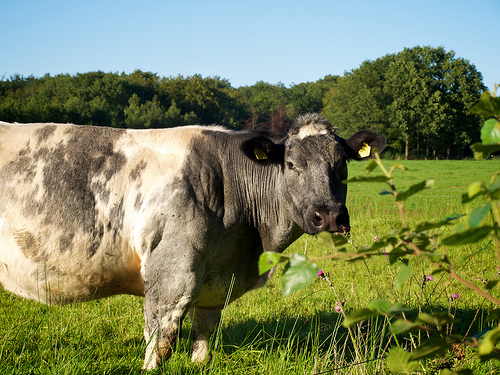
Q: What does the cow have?
A: Spots.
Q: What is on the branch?
A: Leaves.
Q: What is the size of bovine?
A: Very large.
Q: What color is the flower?
A: Pink.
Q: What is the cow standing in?
A: Meadow.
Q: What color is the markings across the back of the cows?
A: Grey.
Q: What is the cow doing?
A: Turning head.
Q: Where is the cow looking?
A: At the camera.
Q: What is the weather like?
A: Clear skies sunny day.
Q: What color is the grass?
A: Bright Green.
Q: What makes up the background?
A: Large trees.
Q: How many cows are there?
A: 1.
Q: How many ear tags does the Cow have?
A: 2.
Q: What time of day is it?
A: Morning.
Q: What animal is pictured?
A: A cow.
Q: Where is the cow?
A: In a field.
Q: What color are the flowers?
A: Pink.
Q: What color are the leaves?
A: Green.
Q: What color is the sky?
A: Blue.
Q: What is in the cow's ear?
A: A yellow tag.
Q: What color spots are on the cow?
A: Grey.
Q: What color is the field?
A: Green.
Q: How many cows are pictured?
A: One.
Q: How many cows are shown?
A: 1.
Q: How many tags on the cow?
A: 2.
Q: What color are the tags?
A: Yellow.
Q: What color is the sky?
A: Blue.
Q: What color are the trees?
A: Green.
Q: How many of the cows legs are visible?
A: 2.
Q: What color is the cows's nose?
A: Black.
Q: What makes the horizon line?
A: Trees.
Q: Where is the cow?
A: In grass field.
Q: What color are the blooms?
A: Purple.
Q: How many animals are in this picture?
A: One.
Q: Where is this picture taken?
A: On a farm.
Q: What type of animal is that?
A: A cow.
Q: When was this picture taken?
A: Daytime.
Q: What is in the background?
A: Trees.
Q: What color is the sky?
A: Blue.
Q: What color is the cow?
A: Black and white.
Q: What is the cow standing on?
A: Grass.